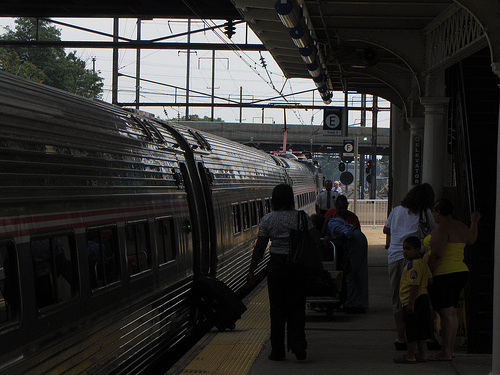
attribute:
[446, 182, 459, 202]
ground — silver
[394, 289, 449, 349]
shorts — black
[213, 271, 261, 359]
line — yellow, wide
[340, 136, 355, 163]
sign — hanging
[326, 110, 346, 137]
sign — hanging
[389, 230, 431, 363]
boy — dark skinned, young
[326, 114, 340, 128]
circle — white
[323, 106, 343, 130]
sign — black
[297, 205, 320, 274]
purse — black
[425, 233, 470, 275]
shirt — yellow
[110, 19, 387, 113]
scaffolding — metal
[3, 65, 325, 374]
train — rounded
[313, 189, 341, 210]
shirt — white